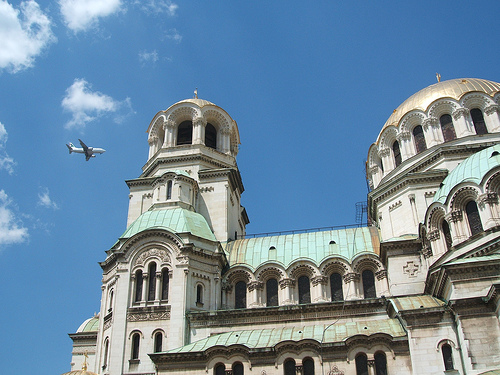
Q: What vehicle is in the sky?
A: Airplane.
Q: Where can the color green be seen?
A: On the roof of the building.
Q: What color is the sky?
A: Blue.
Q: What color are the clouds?
A: White.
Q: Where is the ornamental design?
A: Around the windows.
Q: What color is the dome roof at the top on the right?
A: Gold.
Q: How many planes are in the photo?
A: One.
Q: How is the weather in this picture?
A: Partly cloudy.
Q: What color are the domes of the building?
A: Gold.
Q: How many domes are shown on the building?
A: Two.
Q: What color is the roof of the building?
A: Green.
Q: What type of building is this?
A: Church.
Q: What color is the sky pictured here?
A: Blue.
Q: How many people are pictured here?
A: Zero.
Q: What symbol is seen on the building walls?
A: Cross.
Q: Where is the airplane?
A: Above the building.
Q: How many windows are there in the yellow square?
A: 9.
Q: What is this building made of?
A: Stone.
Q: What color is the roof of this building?
A: Green.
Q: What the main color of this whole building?
A: Tan and green.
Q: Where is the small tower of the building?
A: Left upper top.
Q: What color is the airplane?
A: White.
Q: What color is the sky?
A: Blue.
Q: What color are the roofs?
A: Gold and Green.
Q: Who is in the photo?
A: Nobody.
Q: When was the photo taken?
A: Daytime.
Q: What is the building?
A: A church.